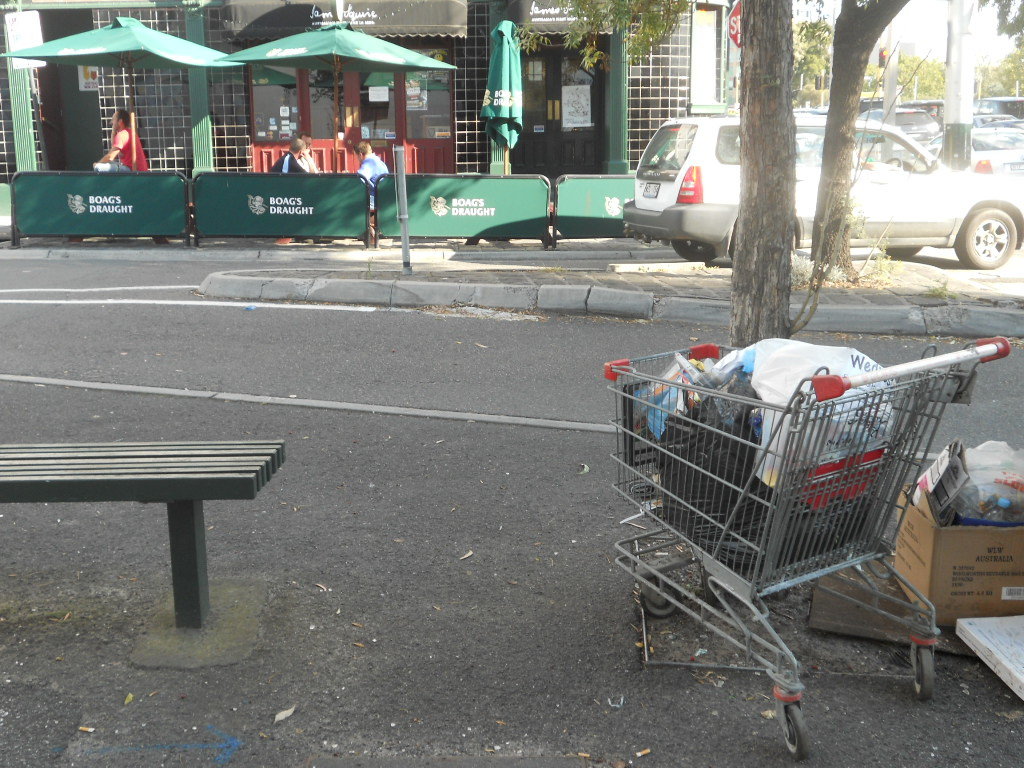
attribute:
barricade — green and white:
[11, 158, 195, 253]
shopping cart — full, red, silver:
[608, 329, 1017, 756]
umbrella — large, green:
[7, 10, 241, 78]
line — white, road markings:
[247, 346, 685, 471]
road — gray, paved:
[89, 290, 659, 518]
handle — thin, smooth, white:
[783, 334, 1021, 398]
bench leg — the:
[129, 509, 244, 658]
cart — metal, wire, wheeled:
[572, 308, 1009, 762]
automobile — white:
[617, 114, 1022, 266]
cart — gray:
[571, 270, 1021, 758]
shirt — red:
[107, 119, 142, 172]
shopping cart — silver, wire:
[596, 376, 972, 705]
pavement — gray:
[34, 329, 990, 740]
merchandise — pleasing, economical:
[658, 361, 888, 502]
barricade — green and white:
[183, 163, 380, 257]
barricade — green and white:
[373, 168, 557, 251]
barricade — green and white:
[555, 168, 636, 248]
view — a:
[6, 346, 691, 481]